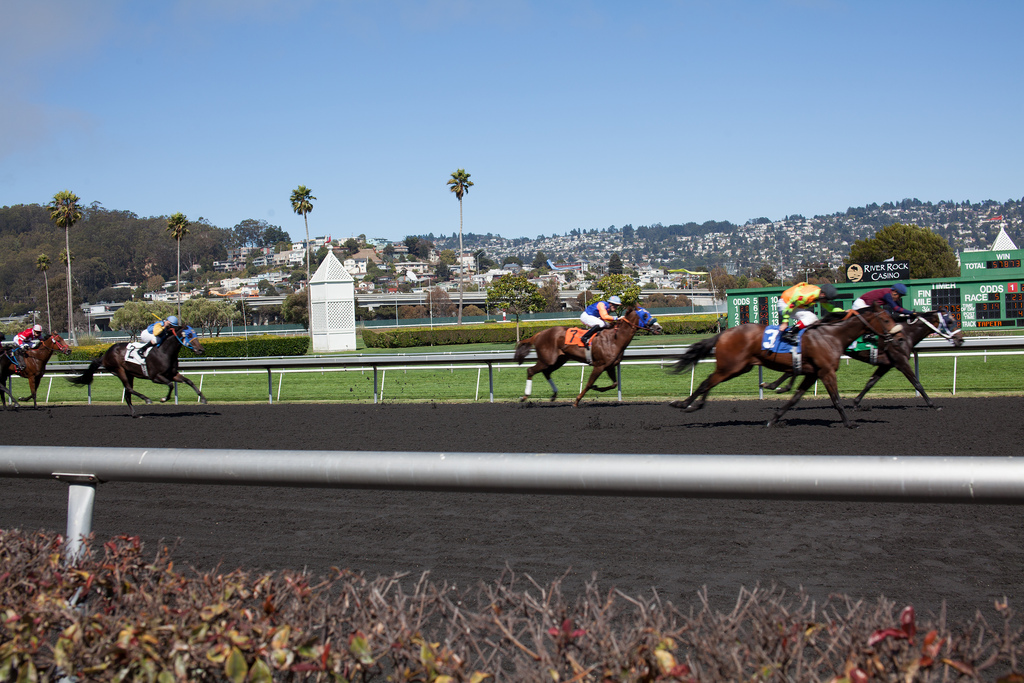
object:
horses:
[0, 331, 77, 409]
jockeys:
[0, 281, 918, 364]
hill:
[0, 196, 1024, 320]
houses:
[46, 199, 1024, 338]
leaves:
[0, 537, 1022, 683]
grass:
[0, 366, 1024, 683]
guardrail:
[0, 338, 1024, 407]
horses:
[61, 323, 206, 419]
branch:
[46, 189, 84, 229]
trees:
[46, 187, 85, 348]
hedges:
[0, 320, 1024, 359]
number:
[762, 329, 778, 348]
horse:
[512, 301, 665, 408]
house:
[725, 248, 1024, 333]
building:
[408, 248, 655, 346]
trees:
[444, 167, 476, 202]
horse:
[660, 298, 906, 434]